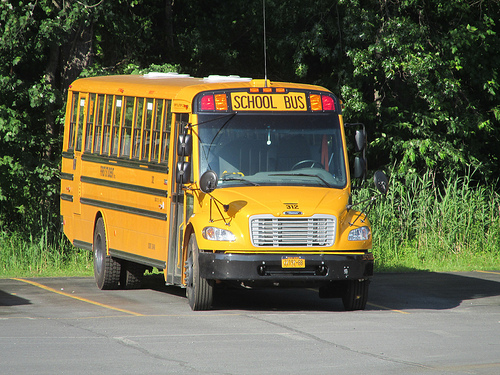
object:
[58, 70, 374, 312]
bus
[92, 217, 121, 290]
tires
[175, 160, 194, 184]
mirror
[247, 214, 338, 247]
grill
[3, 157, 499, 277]
grass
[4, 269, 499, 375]
parking lot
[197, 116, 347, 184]
front windshield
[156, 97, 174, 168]
windows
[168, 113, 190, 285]
door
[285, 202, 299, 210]
312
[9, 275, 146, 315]
line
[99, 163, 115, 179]
writing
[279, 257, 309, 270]
license plate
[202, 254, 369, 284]
bumper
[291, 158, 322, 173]
steering wheel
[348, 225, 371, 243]
left headlight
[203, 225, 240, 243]
right headlight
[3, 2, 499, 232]
bushes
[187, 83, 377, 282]
head